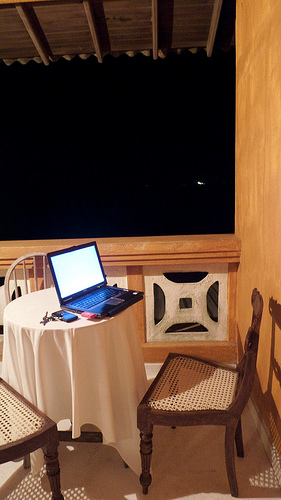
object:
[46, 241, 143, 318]
laptop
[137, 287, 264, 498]
chair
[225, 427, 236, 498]
leg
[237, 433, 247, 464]
leg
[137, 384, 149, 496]
leg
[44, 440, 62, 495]
leg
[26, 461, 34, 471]
leg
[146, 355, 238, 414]
seat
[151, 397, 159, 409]
hole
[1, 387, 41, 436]
seat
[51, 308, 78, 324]
cell phone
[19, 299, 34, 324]
table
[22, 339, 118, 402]
cloth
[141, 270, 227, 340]
design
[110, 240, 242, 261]
railing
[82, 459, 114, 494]
shadow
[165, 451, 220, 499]
floor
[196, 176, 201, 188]
light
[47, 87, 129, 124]
dark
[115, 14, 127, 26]
red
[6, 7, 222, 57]
roof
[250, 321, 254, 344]
wood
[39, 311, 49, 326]
keys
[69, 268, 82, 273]
screen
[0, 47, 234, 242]
balcony